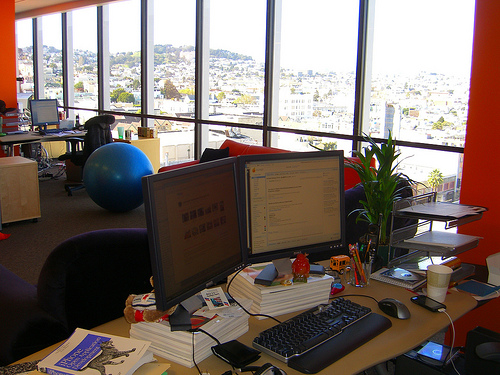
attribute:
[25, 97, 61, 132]
computer moniter — black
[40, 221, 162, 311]
desk chair — black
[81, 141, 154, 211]
ball — dark, blue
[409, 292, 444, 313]
cellphone — black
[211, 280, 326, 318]
keyboard — silver, black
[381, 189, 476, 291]
desktop tray — three tier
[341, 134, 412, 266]
monitor — computer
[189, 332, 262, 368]
leather wallet — black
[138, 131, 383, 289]
desktop — computer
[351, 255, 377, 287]
cup — glass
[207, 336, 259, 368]
wallet — black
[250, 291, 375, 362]
keyboard — black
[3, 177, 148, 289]
floor — carpeted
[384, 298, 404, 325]
mouse — grey, black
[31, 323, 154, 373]
book — white, blue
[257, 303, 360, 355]
keyboard — black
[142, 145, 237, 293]
monitor — Black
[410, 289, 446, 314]
cell phone — cell  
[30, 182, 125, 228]
carpet —  brown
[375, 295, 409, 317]
mouse — black, silver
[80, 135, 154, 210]
blue ball — giant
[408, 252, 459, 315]
cup — plastic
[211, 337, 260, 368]
wallet — black